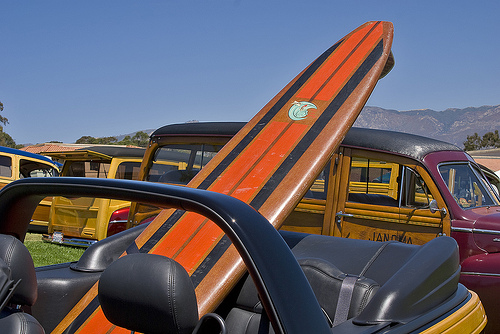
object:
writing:
[366, 229, 413, 248]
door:
[331, 144, 450, 246]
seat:
[291, 232, 462, 324]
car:
[0, 178, 488, 332]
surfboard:
[101, 25, 435, 328]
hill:
[378, 102, 495, 124]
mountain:
[114, 106, 498, 149]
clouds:
[187, 60, 273, 82]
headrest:
[97, 253, 200, 331]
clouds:
[11, 28, 61, 78]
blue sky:
[0, 3, 499, 145]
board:
[46, 21, 396, 331]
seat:
[0, 226, 44, 332]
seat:
[147, 276, 192, 320]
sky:
[100, 88, 130, 110]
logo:
[286, 98, 318, 123]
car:
[43, 141, 211, 249]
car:
[130, 117, 498, 331]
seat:
[90, 246, 203, 332]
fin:
[378, 51, 395, 78]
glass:
[28, 164, 58, 179]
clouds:
[164, 61, 238, 103]